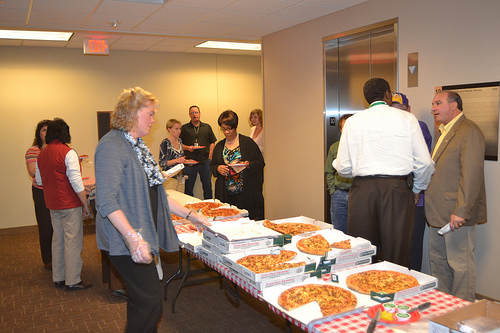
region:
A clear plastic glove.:
[110, 223, 165, 267]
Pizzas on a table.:
[169, 182, 411, 331]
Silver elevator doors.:
[316, 32, 399, 122]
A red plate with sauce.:
[367, 301, 418, 320]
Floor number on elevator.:
[330, 115, 335, 124]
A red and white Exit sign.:
[79, 38, 114, 50]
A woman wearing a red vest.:
[37, 122, 99, 218]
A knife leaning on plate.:
[366, 307, 380, 332]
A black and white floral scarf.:
[122, 134, 167, 187]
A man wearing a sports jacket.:
[430, 90, 486, 225]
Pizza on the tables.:
[173, 186, 450, 325]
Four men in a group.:
[321, 79, 498, 296]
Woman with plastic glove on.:
[120, 230, 157, 270]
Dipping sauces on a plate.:
[366, 300, 423, 330]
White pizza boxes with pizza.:
[176, 196, 455, 323]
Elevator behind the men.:
[318, 16, 433, 271]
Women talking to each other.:
[18, 117, 94, 291]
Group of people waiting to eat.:
[156, 89, 268, 214]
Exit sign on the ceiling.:
[78, 33, 110, 55]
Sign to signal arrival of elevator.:
[402, 52, 421, 90]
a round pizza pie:
[280, 279, 353, 320]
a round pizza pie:
[343, 265, 424, 299]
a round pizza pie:
[299, 229, 348, 259]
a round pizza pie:
[231, 248, 304, 275]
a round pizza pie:
[263, 214, 317, 235]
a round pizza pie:
[197, 205, 237, 220]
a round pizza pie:
[182, 199, 222, 210]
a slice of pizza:
[330, 236, 350, 251]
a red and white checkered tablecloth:
[312, 283, 474, 330]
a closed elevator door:
[319, 22, 401, 222]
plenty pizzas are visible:
[201, 205, 342, 315]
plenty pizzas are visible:
[150, 160, 291, 303]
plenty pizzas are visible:
[205, 265, 335, 321]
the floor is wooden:
[17, 246, 114, 327]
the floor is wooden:
[36, 274, 141, 331]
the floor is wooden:
[21, 238, 188, 325]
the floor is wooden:
[51, 274, 98, 317]